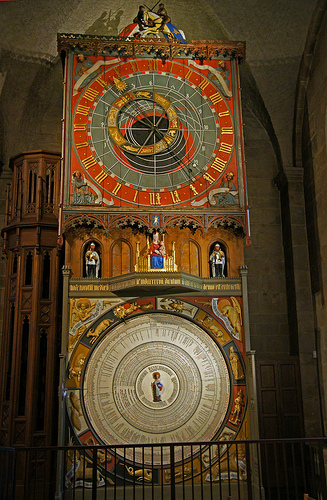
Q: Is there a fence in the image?
A: Yes, there is a fence.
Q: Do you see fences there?
A: Yes, there is a fence.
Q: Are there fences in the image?
A: Yes, there is a fence.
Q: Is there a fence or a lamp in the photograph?
A: Yes, there is a fence.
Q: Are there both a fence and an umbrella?
A: No, there is a fence but no umbrellas.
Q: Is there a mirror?
A: No, there are no mirrors.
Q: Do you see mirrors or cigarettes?
A: No, there are no mirrors or cigarettes.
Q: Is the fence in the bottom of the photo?
A: Yes, the fence is in the bottom of the image.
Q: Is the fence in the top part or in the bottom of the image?
A: The fence is in the bottom of the image.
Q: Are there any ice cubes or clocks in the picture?
A: Yes, there is a clock.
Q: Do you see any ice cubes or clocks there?
A: Yes, there is a clock.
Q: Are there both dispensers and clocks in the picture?
A: No, there is a clock but no dispensers.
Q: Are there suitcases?
A: No, there are no suitcases.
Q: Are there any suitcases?
A: No, there are no suitcases.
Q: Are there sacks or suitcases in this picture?
A: No, there are no suitcases or sacks.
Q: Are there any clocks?
A: Yes, there is a clock.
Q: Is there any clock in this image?
A: Yes, there is a clock.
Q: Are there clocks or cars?
A: Yes, there is a clock.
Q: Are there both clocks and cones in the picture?
A: No, there is a clock but no cones.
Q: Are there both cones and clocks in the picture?
A: No, there is a clock but no cones.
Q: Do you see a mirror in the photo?
A: No, there are no mirrors.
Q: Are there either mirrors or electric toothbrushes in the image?
A: No, there are no mirrors or electric toothbrushes.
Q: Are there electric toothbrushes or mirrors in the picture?
A: No, there are no mirrors or electric toothbrushes.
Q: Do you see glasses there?
A: No, there are no glasses.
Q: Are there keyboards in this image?
A: No, there are no keyboards.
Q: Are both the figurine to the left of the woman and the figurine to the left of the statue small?
A: Yes, both the figurine and the figurine are small.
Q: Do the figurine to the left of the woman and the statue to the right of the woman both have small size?
A: Yes, both the figurine and the statue are small.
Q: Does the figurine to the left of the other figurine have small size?
A: Yes, the figurine is small.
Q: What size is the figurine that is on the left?
A: The figurine is small.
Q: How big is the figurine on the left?
A: The figurine is small.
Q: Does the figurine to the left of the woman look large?
A: No, the figurine is small.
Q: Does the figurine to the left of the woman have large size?
A: No, the figurine is small.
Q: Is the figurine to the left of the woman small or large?
A: The figurine is small.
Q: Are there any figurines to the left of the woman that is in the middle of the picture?
A: Yes, there is a figurine to the left of the woman.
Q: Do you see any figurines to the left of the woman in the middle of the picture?
A: Yes, there is a figurine to the left of the woman.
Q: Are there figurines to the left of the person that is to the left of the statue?
A: Yes, there is a figurine to the left of the woman.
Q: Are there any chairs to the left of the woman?
A: No, there is a figurine to the left of the woman.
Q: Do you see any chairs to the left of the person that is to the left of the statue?
A: No, there is a figurine to the left of the woman.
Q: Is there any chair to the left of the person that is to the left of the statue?
A: No, there is a figurine to the left of the woman.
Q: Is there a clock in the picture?
A: Yes, there is a clock.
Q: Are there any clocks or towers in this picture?
A: Yes, there is a clock.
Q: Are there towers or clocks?
A: Yes, there is a clock.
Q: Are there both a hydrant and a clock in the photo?
A: No, there is a clock but no fire hydrants.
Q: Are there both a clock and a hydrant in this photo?
A: No, there is a clock but no fire hydrants.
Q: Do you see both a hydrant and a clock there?
A: No, there is a clock but no fire hydrants.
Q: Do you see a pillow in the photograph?
A: No, there are no pillows.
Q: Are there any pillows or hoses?
A: No, there are no pillows or hoses.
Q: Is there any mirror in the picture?
A: No, there are no mirrors.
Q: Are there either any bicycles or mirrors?
A: No, there are no mirrors or bicycles.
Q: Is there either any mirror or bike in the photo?
A: No, there are no mirrors or bikes.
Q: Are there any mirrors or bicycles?
A: No, there are no mirrors or bicycles.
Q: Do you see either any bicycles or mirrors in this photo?
A: No, there are no mirrors or bicycles.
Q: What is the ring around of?
A: The ring is around the clock.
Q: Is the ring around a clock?
A: Yes, the ring is around a clock.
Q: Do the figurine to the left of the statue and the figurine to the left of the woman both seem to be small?
A: Yes, both the figurine and the figurine are small.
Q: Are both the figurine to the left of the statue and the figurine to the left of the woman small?
A: Yes, both the figurine and the figurine are small.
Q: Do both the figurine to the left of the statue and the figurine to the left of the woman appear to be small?
A: Yes, both the figurine and the figurine are small.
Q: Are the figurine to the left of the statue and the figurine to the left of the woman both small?
A: Yes, both the figurine and the figurine are small.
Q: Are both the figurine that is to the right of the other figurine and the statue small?
A: Yes, both the figurine and the statue are small.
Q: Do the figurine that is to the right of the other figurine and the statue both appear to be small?
A: Yes, both the figurine and the statue are small.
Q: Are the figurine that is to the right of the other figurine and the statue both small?
A: Yes, both the figurine and the statue are small.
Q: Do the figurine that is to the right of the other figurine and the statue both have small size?
A: Yes, both the figurine and the statue are small.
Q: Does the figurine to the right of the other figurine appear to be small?
A: Yes, the figurine is small.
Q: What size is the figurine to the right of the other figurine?
A: The figurine is small.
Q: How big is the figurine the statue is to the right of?
A: The figurine is small.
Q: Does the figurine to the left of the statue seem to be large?
A: No, the figurine is small.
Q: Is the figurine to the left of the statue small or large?
A: The figurine is small.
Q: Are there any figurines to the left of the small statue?
A: Yes, there is a figurine to the left of the statue.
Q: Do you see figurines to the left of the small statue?
A: Yes, there is a figurine to the left of the statue.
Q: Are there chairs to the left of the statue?
A: No, there is a figurine to the left of the statue.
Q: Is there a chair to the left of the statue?
A: No, there is a figurine to the left of the statue.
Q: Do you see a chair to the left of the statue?
A: No, there is a figurine to the left of the statue.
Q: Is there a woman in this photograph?
A: Yes, there is a woman.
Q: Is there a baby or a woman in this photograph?
A: Yes, there is a woman.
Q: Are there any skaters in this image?
A: No, there are no skaters.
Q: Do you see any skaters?
A: No, there are no skaters.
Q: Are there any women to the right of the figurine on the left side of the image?
A: Yes, there is a woman to the right of the figurine.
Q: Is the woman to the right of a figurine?
A: Yes, the woman is to the right of a figurine.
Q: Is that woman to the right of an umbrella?
A: No, the woman is to the right of a figurine.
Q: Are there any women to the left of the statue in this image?
A: Yes, there is a woman to the left of the statue.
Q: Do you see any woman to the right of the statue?
A: No, the woman is to the left of the statue.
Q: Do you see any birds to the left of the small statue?
A: No, there is a woman to the left of the statue.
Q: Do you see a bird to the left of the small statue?
A: No, there is a woman to the left of the statue.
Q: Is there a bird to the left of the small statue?
A: No, there is a woman to the left of the statue.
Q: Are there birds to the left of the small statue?
A: No, there is a woman to the left of the statue.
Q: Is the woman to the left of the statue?
A: Yes, the woman is to the left of the statue.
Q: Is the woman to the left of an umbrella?
A: No, the woman is to the left of the statue.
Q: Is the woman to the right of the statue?
A: No, the woman is to the left of the statue.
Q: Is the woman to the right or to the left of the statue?
A: The woman is to the left of the statue.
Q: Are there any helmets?
A: No, there are no helmets.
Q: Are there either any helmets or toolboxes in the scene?
A: No, there are no helmets or toolboxes.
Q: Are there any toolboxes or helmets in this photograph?
A: No, there are no helmets or toolboxes.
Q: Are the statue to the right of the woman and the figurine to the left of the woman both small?
A: Yes, both the statue and the figurine are small.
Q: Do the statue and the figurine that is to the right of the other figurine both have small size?
A: Yes, both the statue and the figurine are small.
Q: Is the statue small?
A: Yes, the statue is small.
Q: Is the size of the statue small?
A: Yes, the statue is small.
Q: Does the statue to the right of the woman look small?
A: Yes, the statue is small.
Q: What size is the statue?
A: The statue is small.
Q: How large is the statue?
A: The statue is small.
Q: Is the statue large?
A: No, the statue is small.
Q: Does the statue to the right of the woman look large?
A: No, the statue is small.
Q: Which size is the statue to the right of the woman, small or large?
A: The statue is small.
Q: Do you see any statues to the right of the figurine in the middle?
A: Yes, there is a statue to the right of the figurine.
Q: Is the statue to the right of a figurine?
A: Yes, the statue is to the right of a figurine.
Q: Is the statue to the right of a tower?
A: No, the statue is to the right of a figurine.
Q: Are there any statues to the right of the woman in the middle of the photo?
A: Yes, there is a statue to the right of the woman.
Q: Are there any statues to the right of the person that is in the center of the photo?
A: Yes, there is a statue to the right of the woman.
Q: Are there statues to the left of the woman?
A: No, the statue is to the right of the woman.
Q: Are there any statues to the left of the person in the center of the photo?
A: No, the statue is to the right of the woman.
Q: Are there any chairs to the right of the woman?
A: No, there is a statue to the right of the woman.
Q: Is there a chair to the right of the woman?
A: No, there is a statue to the right of the woman.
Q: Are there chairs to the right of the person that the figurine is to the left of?
A: No, there is a statue to the right of the woman.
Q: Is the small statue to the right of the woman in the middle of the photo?
A: Yes, the statue is to the right of the woman.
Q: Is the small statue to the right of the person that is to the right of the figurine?
A: Yes, the statue is to the right of the woman.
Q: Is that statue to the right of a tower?
A: No, the statue is to the right of the woman.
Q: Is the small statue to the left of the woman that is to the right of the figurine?
A: No, the statue is to the right of the woman.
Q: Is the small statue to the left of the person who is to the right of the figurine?
A: No, the statue is to the right of the woman.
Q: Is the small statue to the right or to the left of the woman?
A: The statue is to the right of the woman.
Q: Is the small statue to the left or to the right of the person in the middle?
A: The statue is to the right of the woman.